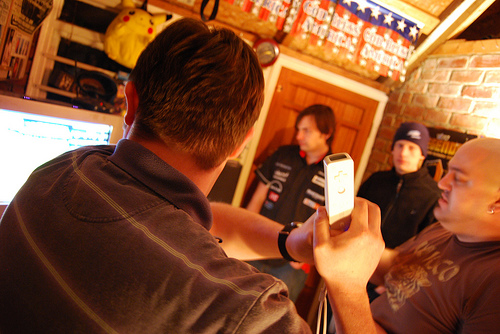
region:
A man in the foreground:
[7, 0, 384, 331]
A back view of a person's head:
[1, 13, 383, 331]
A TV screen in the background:
[0, 84, 134, 241]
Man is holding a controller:
[295, 124, 388, 296]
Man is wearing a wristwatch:
[265, 210, 305, 270]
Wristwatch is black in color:
[265, 208, 310, 268]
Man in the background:
[430, 132, 499, 244]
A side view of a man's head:
[422, 124, 499, 251]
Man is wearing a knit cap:
[373, 109, 435, 194]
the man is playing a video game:
[15, 16, 413, 306]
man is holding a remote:
[246, 110, 411, 309]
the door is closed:
[245, 51, 390, 228]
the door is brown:
[238, 40, 378, 175]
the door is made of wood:
[240, 58, 377, 177]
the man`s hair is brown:
[105, 17, 270, 171]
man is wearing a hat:
[344, 92, 428, 181]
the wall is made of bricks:
[390, 55, 490, 132]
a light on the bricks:
[438, 57, 496, 127]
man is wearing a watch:
[265, 201, 317, 257]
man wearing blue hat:
[366, 95, 448, 247]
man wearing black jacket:
[346, 71, 454, 260]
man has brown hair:
[268, 75, 350, 187]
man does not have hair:
[425, 114, 499, 267]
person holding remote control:
[58, 8, 420, 325]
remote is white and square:
[290, 116, 382, 287]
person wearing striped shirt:
[0, 2, 332, 326]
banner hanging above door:
[188, 3, 499, 240]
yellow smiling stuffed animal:
[91, 3, 191, 88]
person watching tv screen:
[0, 0, 358, 325]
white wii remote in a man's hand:
[321, 150, 358, 232]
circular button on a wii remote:
[335, 181, 347, 197]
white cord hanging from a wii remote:
[314, 283, 329, 332]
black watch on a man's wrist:
[275, 220, 305, 263]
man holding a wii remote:
[0, 16, 390, 332]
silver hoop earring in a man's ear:
[485, 205, 494, 215]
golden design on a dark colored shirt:
[380, 238, 467, 309]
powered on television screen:
[1, 93, 126, 219]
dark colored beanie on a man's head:
[389, 120, 431, 157]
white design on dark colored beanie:
[405, 129, 424, 141]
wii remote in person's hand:
[316, 139, 359, 219]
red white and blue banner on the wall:
[347, 5, 415, 87]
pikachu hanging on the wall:
[102, 3, 162, 65]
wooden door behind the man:
[274, 63, 377, 174]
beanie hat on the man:
[390, 118, 430, 156]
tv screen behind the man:
[3, 85, 121, 221]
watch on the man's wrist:
[271, 218, 311, 257]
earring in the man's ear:
[483, 203, 497, 215]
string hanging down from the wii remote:
[310, 271, 334, 331]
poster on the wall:
[425, 125, 452, 177]